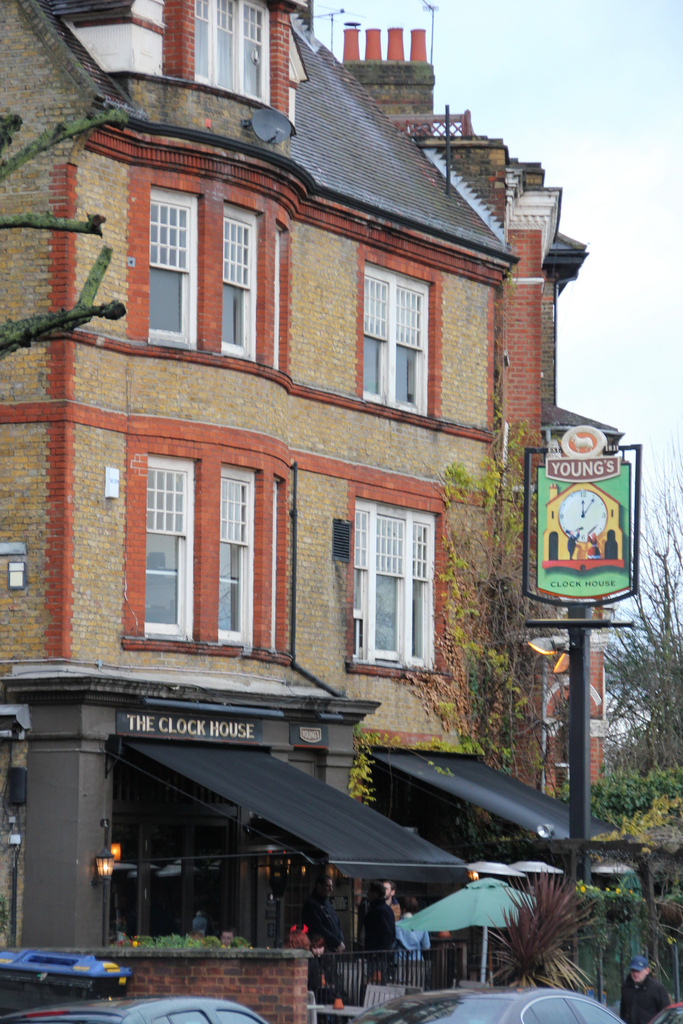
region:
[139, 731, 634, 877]
black awnings on the building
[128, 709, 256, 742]
lettering on the building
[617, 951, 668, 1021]
man wearing black shirt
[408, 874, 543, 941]
green umbrella by the black railing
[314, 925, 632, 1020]
black railing beside the building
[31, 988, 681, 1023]
cars parked beside the building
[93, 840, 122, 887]
black light fixture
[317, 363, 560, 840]
ivy growing on the building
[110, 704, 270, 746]
Sign says The Clock House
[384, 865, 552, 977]
Table umbrella is green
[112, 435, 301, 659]
Windows above the entryway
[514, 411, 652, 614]
Sign post on the street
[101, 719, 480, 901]
Black awning on the entryway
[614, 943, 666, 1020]
Man walking down the street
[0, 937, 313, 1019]
Brick wall on sidewalk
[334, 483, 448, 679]
Window with white frames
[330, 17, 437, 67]
Four stacks on the roof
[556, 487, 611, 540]
Picture of clock on sign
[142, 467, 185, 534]
glass is clean and clear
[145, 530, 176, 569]
glass is clean and clear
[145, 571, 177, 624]
glass is clean and clear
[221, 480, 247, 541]
glass is clean and clear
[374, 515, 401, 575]
glass is clean and clear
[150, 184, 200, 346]
window on the wall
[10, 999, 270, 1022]
a car is parked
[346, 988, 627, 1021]
the car is parked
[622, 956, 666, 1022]
a man is walking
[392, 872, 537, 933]
the umbrella is green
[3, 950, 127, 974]
yellow and blue lid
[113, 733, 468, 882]
the awning is black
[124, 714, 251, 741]
the text is white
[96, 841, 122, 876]
the lights are on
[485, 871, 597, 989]
the plant is brown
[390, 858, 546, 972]
umbrella outside the building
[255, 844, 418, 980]
people next to building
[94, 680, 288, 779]
words on the building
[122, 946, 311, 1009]
bricks next to building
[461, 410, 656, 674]
sign next to the building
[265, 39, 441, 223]
roof of the building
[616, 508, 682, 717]
branches next to the building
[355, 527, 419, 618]
a window on the building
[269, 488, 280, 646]
a window on the building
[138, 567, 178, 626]
glass window on the building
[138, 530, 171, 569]
glass window on the building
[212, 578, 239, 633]
glass window on the building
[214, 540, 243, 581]
glass window on the building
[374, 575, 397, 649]
glass window on the building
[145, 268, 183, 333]
glass window on the building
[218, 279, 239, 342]
glass window on the building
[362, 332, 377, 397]
glass window on the building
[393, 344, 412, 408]
glass window on the building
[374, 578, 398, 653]
glass window on the building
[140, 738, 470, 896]
black awning on side of building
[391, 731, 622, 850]
black awning on side of building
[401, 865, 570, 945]
open green umbrella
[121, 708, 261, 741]
black sign with gold letters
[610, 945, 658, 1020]
man walking with hat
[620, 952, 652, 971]
blue baseball hat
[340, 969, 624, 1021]
top of black car